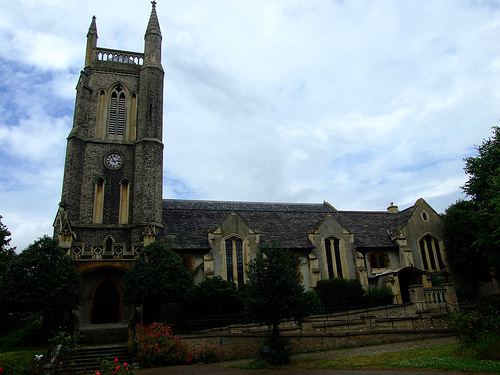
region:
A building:
[98, 184, 285, 358]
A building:
[185, 252, 295, 363]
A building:
[158, 170, 320, 314]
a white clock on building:
[100, 145, 125, 172]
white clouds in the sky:
[241, 42, 408, 114]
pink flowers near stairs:
[129, 323, 194, 365]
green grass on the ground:
[421, 356, 464, 368]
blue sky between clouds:
[5, 104, 18, 116]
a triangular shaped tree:
[116, 239, 203, 328]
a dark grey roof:
[257, 209, 307, 230]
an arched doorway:
[83, 271, 125, 328]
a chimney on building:
[386, 202, 399, 212]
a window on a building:
[218, 233, 252, 288]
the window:
[417, 211, 441, 231]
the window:
[419, 215, 429, 221]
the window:
[424, 207, 429, 234]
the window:
[414, 204, 429, 234]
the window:
[419, 201, 434, 236]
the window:
[408, 208, 430, 220]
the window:
[408, 213, 453, 222]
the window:
[419, 204, 452, 238]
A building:
[114, 220, 412, 347]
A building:
[184, 308, 296, 368]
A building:
[124, 216, 276, 317]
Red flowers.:
[136, 320, 186, 360]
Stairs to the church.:
[65, 325, 120, 365]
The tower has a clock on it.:
[100, 145, 125, 170]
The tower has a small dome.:
[100, 52, 140, 62]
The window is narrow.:
[220, 230, 245, 290]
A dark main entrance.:
[85, 270, 125, 330]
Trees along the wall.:
[135, 260, 385, 315]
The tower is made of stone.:
[55, 0, 160, 240]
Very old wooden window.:
[90, 80, 135, 140]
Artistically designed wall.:
[61, 230, 141, 260]